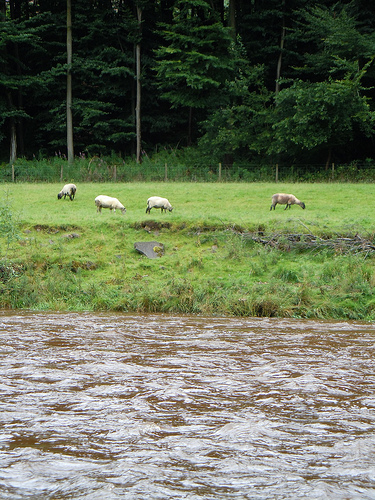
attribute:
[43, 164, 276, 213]
sheep — group, eating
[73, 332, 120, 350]
river — rippled, brown, coast, view, clear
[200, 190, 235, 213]
grass — field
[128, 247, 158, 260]
rock — large, view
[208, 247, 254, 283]
twigs — brown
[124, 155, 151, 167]
trunk — big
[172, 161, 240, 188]
fence — small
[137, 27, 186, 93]
tree — back, green